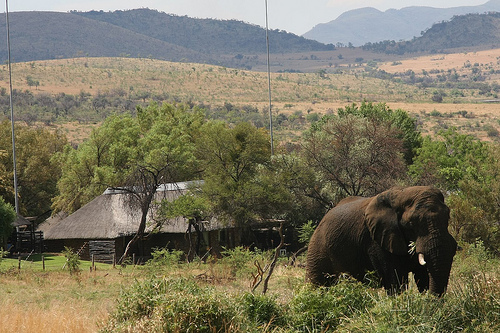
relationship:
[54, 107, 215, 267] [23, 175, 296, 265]
tree in front of hut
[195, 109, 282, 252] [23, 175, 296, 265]
tree in front of hut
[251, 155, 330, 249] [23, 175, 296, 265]
trees in front of hut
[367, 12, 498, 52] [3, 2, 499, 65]
mountain in range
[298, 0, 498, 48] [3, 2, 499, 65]
mountain in range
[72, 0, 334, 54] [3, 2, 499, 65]
mountain in range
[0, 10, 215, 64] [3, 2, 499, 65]
mountain in range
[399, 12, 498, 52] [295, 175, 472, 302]
mountain behind elephants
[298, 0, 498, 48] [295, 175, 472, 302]
mountain behind elephants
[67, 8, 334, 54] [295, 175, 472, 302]
mountain behind elephants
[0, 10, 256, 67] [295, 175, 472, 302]
mountain behind elephants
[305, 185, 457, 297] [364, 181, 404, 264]
elephant has ear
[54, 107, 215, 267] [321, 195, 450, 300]
tree behind elephant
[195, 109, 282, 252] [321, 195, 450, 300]
tree behind elephant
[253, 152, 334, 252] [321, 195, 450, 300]
tree behind elephant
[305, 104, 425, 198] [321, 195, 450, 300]
tree behind elephant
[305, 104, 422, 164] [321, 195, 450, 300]
tree behind elephant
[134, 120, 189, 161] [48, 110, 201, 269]
leaves in tree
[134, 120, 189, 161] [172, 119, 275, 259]
leaves in tree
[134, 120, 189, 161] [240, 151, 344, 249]
leaves in tree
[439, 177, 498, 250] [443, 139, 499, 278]
leaves in tree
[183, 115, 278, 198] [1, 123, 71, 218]
leaves in tree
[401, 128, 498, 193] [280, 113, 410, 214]
leaves in tree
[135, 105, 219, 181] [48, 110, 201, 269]
leaves in tree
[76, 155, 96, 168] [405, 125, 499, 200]
leaves in tree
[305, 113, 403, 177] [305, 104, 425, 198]
leaves in tree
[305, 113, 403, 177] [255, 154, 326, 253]
leaves in tree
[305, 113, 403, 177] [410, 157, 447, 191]
leaves in tree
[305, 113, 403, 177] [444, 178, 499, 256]
leaves in tree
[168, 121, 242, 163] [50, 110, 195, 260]
green leaves in tree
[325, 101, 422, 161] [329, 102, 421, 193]
leaves in tree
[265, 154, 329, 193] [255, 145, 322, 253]
leaves in tree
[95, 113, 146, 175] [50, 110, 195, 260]
leaves in tree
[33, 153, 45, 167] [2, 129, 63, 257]
leaves in tree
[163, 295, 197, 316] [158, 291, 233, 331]
leaves in bush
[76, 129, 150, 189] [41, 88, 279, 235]
leaves in trees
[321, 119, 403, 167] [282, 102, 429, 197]
leaves in trees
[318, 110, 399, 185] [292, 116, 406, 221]
leaves in tree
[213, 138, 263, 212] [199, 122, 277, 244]
leaves in tree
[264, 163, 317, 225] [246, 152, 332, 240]
leaves in tree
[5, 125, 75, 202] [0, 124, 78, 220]
leaves in tree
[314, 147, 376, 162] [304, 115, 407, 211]
leaves in tree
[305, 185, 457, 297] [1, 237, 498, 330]
elephant in grass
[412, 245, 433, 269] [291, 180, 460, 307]
tusk on elephant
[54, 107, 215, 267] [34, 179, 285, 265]
tree around hut